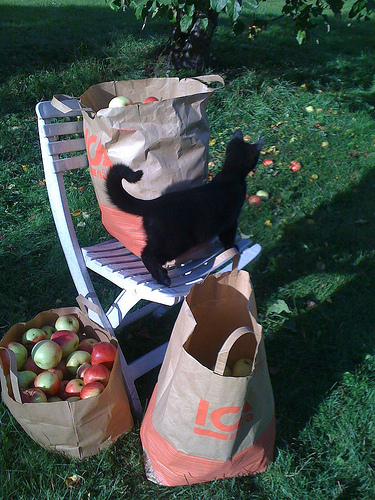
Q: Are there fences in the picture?
A: No, there are no fences.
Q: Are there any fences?
A: No, there are no fences.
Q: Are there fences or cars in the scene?
A: No, there are no fences or cars.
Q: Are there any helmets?
A: No, there are no helmets.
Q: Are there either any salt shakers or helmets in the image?
A: No, there are no helmets or salt shakers.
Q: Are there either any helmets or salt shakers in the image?
A: No, there are no helmets or salt shakers.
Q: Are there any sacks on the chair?
A: Yes, there is a sack on the chair.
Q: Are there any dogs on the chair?
A: No, there is a sack on the chair.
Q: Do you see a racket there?
A: No, there are no rackets.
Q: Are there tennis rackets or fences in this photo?
A: No, there are no tennis rackets or fences.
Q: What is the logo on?
A: The logo is on the sack.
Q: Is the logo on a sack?
A: Yes, the logo is on a sack.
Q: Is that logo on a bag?
A: No, the logo is on a sack.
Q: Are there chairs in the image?
A: Yes, there is a chair.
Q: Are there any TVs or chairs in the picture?
A: Yes, there is a chair.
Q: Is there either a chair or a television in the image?
A: Yes, there is a chair.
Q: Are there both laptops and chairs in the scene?
A: No, there is a chair but no laptops.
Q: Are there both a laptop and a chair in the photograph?
A: No, there is a chair but no laptops.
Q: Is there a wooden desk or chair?
A: Yes, there is a wood chair.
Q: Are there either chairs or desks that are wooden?
A: Yes, the chair is wooden.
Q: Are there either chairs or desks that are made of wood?
A: Yes, the chair is made of wood.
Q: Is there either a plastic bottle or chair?
A: Yes, there is a plastic chair.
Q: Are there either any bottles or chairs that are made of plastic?
A: Yes, the chair is made of plastic.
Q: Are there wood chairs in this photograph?
A: Yes, there is a wood chair.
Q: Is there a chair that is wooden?
A: Yes, there is a chair that is wooden.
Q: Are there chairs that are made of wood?
A: Yes, there is a chair that is made of wood.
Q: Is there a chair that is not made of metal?
A: Yes, there is a chair that is made of wood.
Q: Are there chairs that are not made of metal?
A: Yes, there is a chair that is made of wood.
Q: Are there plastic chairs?
A: Yes, there is a chair that is made of plastic.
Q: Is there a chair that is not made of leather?
A: Yes, there is a chair that is made of plastic.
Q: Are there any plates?
A: No, there are no plates.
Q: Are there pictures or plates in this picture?
A: No, there are no plates or pictures.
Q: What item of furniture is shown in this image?
A: The piece of furniture is a chair.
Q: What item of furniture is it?
A: The piece of furniture is a chair.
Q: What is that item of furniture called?
A: This is a chair.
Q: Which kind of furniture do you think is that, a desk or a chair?
A: This is a chair.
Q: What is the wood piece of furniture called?
A: The piece of furniture is a chair.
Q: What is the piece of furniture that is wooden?
A: The piece of furniture is a chair.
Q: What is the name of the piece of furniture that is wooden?
A: The piece of furniture is a chair.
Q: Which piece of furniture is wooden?
A: The piece of furniture is a chair.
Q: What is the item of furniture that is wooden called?
A: The piece of furniture is a chair.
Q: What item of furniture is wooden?
A: The piece of furniture is a chair.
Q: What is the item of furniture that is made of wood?
A: The piece of furniture is a chair.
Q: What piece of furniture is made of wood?
A: The piece of furniture is a chair.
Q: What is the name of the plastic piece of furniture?
A: The piece of furniture is a chair.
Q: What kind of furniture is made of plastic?
A: The furniture is a chair.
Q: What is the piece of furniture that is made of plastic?
A: The piece of furniture is a chair.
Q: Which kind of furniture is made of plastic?
A: The furniture is a chair.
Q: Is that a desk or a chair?
A: That is a chair.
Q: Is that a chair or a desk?
A: That is a chair.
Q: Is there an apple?
A: Yes, there is an apple.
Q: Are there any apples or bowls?
A: Yes, there is an apple.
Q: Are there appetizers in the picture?
A: No, there are no appetizers.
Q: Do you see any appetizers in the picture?
A: No, there are no appetizers.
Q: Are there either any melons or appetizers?
A: No, there are no appetizers or melons.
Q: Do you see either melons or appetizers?
A: No, there are no appetizers or melons.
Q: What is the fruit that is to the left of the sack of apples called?
A: The fruit is an apple.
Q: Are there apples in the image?
A: Yes, there is an apple.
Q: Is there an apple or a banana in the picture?
A: Yes, there is an apple.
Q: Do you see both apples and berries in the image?
A: No, there is an apple but no berries.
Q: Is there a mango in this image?
A: No, there are no mangoes.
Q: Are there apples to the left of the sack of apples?
A: Yes, there is an apple to the left of the sack.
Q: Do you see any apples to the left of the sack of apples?
A: Yes, there is an apple to the left of the sack.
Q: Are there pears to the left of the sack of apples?
A: No, there is an apple to the left of the sack.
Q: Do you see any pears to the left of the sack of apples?
A: No, there is an apple to the left of the sack.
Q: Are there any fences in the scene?
A: No, there are no fences.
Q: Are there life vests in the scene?
A: No, there are no life vests.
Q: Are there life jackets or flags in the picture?
A: No, there are no life jackets or flags.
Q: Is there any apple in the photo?
A: Yes, there are apples.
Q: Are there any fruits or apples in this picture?
A: Yes, there are apples.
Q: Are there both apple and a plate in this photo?
A: No, there are apples but no plates.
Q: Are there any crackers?
A: No, there are no crackers.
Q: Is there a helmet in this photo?
A: No, there are no helmets.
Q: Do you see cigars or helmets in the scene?
A: No, there are no helmets or cigars.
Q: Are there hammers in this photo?
A: No, there are no hammers.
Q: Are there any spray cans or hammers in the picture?
A: No, there are no hammers or spray cans.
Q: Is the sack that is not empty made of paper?
A: Yes, the sack is made of paper.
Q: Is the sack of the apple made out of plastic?
A: No, the sack is made of paper.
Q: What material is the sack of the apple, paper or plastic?
A: The sack is made of paper.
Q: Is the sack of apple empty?
A: No, the sack is full.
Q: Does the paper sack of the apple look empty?
A: No, the sack is full.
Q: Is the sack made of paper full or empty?
A: The sack is full.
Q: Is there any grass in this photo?
A: Yes, there is grass.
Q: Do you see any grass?
A: Yes, there is grass.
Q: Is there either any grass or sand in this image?
A: Yes, there is grass.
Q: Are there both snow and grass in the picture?
A: No, there is grass but no snow.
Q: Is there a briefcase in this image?
A: No, there are no briefcases.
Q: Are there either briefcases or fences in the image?
A: No, there are no briefcases or fences.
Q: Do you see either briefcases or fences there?
A: No, there are no briefcases or fences.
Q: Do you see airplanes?
A: No, there are no airplanes.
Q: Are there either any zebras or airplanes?
A: No, there are no airplanes or zebras.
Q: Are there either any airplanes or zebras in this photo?
A: No, there are no airplanes or zebras.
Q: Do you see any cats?
A: Yes, there is a cat.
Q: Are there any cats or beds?
A: Yes, there is a cat.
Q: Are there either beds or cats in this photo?
A: Yes, there is a cat.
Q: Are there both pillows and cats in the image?
A: No, there is a cat but no pillows.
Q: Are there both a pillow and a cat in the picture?
A: No, there is a cat but no pillows.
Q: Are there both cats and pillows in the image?
A: No, there is a cat but no pillows.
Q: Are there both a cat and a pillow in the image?
A: No, there is a cat but no pillows.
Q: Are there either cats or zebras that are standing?
A: Yes, the cat is standing.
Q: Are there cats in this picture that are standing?
A: Yes, there is a cat that is standing.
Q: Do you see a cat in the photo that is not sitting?
A: Yes, there is a cat that is standing .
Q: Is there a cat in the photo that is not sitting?
A: Yes, there is a cat that is standing.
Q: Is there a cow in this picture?
A: No, there are no cows.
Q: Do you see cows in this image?
A: No, there are no cows.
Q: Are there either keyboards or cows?
A: No, there are no cows or keyboards.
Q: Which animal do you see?
A: The animal is a cat.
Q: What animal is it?
A: The animal is a cat.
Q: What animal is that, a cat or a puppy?
A: That is a cat.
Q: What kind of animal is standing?
A: The animal is a cat.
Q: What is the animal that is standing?
A: The animal is a cat.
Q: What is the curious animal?
A: The animal is a cat.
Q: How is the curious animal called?
A: The animal is a cat.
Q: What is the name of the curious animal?
A: The animal is a cat.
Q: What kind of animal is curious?
A: The animal is a cat.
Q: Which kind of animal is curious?
A: The animal is a cat.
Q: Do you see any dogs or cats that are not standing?
A: No, there is a cat but it is standing.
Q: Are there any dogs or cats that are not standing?
A: No, there is a cat but it is standing.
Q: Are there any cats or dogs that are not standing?
A: No, there is a cat but it is standing.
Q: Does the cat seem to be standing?
A: Yes, the cat is standing.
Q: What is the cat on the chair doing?
A: The cat is standing.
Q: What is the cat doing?
A: The cat is standing.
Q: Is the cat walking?
A: No, the cat is standing.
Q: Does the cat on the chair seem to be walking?
A: No, the cat is standing.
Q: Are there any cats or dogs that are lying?
A: No, there is a cat but it is standing.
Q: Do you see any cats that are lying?
A: No, there is a cat but it is standing.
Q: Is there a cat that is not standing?
A: No, there is a cat but it is standing.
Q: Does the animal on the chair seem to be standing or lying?
A: The cat is standing.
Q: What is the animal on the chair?
A: The animal is a cat.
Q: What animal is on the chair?
A: The animal is a cat.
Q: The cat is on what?
A: The cat is on the chair.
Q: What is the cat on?
A: The cat is on the chair.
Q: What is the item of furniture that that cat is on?
A: The piece of furniture is a chair.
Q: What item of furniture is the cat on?
A: The cat is on the chair.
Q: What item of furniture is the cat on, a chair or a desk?
A: The cat is on a chair.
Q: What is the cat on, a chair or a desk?
A: The cat is on a chair.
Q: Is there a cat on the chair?
A: Yes, there is a cat on the chair.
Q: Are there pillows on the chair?
A: No, there is a cat on the chair.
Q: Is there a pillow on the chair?
A: No, there is a cat on the chair.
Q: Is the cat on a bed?
A: No, the cat is on a chair.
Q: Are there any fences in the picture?
A: No, there are no fences.